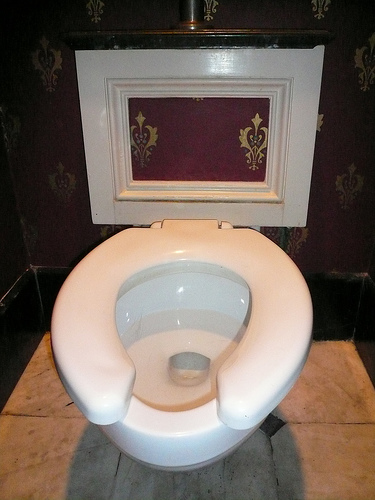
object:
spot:
[258, 413, 286, 436]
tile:
[270, 421, 375, 497]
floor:
[0, 411, 112, 498]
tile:
[310, 266, 366, 338]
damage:
[258, 410, 288, 440]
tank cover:
[57, 30, 326, 49]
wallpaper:
[126, 98, 267, 182]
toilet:
[51, 218, 322, 410]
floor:
[0, 413, 122, 499]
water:
[124, 310, 247, 411]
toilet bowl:
[51, 220, 313, 471]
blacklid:
[59, 0, 338, 51]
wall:
[5, 7, 371, 247]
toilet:
[39, 213, 321, 480]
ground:
[263, 85, 296, 198]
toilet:
[29, 109, 318, 475]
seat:
[49, 288, 314, 493]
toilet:
[47, 29, 338, 475]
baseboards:
[0, 263, 48, 411]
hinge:
[150, 218, 233, 232]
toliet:
[50, 213, 313, 472]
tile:
[270, 340, 374, 422]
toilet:
[48, 178, 329, 473]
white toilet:
[48, 206, 321, 477]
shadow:
[0, 139, 77, 229]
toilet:
[49, 225, 315, 476]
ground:
[0, 331, 375, 499]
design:
[124, 111, 159, 169]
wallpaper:
[1, 0, 374, 268]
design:
[335, 162, 366, 213]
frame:
[71, 43, 325, 231]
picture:
[73, 107, 325, 288]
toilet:
[57, 229, 322, 466]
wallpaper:
[136, 102, 264, 172]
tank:
[67, 35, 326, 224]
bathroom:
[0, 1, 375, 499]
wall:
[3, 4, 363, 272]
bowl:
[122, 284, 225, 356]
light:
[84, 393, 124, 426]